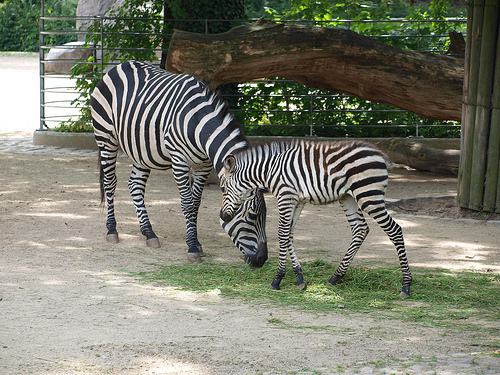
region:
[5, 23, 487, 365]
A mother and baby zebra in a park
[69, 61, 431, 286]
An adult zebra and a young zebra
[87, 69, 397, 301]
The zebras have stripes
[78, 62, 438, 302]
The zebras are black and white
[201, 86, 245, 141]
A short mane on the zebra's back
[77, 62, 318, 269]
The adult zebra is grazing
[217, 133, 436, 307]
The young zebra is walking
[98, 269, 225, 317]
A patch of light amid shadows on the ground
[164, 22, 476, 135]
A large wooden branch behind the zebras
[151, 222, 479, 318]
A small patch of grass beneath the zebras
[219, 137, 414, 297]
A very young zebra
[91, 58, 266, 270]
An adult zebra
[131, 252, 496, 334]
Some grass on the ground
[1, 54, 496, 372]
A dirt landscape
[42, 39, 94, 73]
A large rock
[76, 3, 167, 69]
A very large boulder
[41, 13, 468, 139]
A metal fence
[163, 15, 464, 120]
A very large wooden log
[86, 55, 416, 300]
A pair of zebras in an enclosure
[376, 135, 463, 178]
A large log on the ground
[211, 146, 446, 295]
this is a zebra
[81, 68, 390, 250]
the zebras are two in number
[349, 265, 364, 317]
this is a grass area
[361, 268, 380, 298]
the grass is green in color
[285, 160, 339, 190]
the zebra has white and black strips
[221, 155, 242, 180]
this is the ear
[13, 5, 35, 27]
this is a tree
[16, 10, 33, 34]
the leaves are green in color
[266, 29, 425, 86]
this is a wood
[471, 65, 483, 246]
this is a pole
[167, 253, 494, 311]
Grass beneath the zebras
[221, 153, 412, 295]
A small zebra on the grass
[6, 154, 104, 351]
A shadow on the ground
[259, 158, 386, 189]
The zebra has black and white stripes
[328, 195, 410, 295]
The back legs of the zebra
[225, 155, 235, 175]
The left ear of the zebra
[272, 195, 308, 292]
The front legs of the zebra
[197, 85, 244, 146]
The mane of the zebra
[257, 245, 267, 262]
The nose of the zebra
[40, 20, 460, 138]
A fence behind the zebras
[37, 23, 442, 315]
two zebras are playing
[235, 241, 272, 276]
the nose is black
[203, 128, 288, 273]
the zebras heads are down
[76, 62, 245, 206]
the zebra is black and white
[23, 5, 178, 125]
the fence is grey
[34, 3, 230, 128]
a fence behind the zebra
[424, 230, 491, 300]
sun is on the ground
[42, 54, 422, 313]
zebras are in the shade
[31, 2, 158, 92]
big rocks in the background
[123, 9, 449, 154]
a big tree trunk